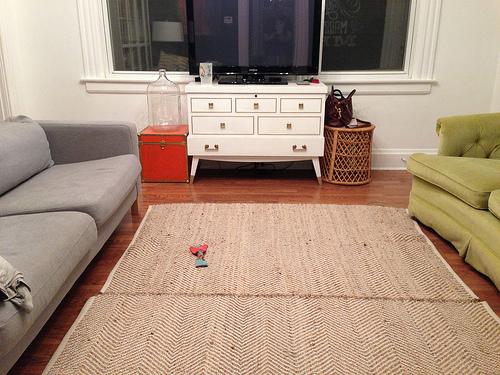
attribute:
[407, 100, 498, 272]
sofa — lime green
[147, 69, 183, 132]
bottle — large, empty, glass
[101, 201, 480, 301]
rug — tan, burlap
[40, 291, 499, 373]
rug — burlap, tan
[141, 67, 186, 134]
jug — large 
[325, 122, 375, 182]
stool — straw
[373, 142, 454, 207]
ground — bamboo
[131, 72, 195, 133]
bottle — glass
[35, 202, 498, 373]
rugs — woven 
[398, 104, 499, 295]
sofa — green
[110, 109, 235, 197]
chest — red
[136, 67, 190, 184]
chest jug — red 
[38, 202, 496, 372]
area rug — square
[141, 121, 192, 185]
storage box — square, orange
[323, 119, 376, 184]
basket — round, wicker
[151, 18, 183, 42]
lamp — white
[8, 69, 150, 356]
couch — gray 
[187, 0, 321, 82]
tv — flat screen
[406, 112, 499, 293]
loveseat — green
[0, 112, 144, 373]
couch — grey, gray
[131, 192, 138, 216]
leg — wooden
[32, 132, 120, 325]
couch — grey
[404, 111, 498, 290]
couch — green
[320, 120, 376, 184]
container — round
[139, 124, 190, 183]
chest — white 